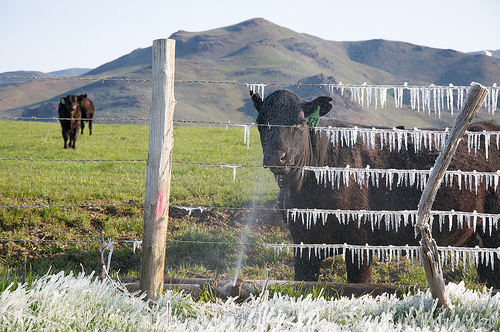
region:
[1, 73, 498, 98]
a long strand of metal wire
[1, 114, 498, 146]
a long strand of metal wire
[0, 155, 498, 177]
a long strand of metal wire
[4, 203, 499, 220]
a long strand of metal wire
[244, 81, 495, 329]
a cow behind a fence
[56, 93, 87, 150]
a cow behind a fence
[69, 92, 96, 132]
a cow behind a fence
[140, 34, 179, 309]
a wooden pole for a fence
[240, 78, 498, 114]
a strand of wire with icicles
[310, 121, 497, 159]
a strand of wire with icicles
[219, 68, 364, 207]
The cow is dark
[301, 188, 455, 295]
The fence has icicles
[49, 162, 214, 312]
The grass is green and cut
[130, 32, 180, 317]
The post is wooden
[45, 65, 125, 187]
The cow is in the back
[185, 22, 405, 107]
Hills are in the back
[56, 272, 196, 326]
The ground is part white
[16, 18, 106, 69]
The sky is light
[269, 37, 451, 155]
The hills are dark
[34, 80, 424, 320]
The cows are in the field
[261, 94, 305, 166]
a cow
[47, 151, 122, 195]
a field of grass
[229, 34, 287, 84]
the mountains is brown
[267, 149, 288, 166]
nose of the cow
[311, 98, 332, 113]
the ear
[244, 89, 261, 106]
the right ear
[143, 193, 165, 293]
a pole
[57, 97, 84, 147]
a cow standing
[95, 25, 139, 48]
the sky is clear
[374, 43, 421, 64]
the mountain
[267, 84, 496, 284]
brown cow near fence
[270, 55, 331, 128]
cow has brown ears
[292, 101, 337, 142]
yellow tag in ear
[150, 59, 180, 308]
white post on fence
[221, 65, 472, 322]
grey wires on fence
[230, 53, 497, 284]
ice on grey wires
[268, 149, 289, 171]
cow has black nose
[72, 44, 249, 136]
brown and green hill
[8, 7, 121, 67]
grey and white sky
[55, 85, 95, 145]
two cows in the distance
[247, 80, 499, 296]
black cow standing behind the fence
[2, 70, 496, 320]
fence is filled with icicles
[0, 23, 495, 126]
mountain range in the distance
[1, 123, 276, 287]
large green open field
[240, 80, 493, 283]
black cow standing on the grass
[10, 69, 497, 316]
fence in front of the field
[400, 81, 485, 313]
stick leaning against the fence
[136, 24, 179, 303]
wooden fencse post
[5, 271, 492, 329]
the grass on the ground is frosted